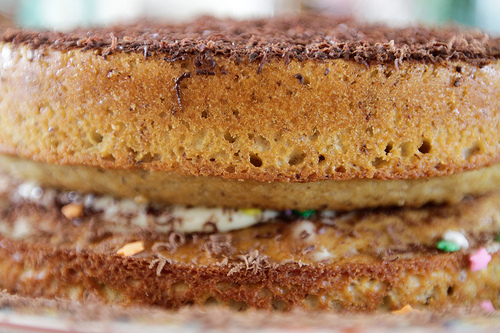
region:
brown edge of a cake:
[2, 43, 493, 174]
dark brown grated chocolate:
[20, 16, 492, 73]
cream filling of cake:
[7, 175, 289, 244]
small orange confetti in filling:
[57, 200, 161, 257]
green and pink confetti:
[432, 236, 493, 270]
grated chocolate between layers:
[146, 224, 277, 275]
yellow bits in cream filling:
[232, 204, 263, 225]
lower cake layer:
[4, 206, 499, 318]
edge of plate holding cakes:
[0, 296, 495, 330]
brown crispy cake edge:
[8, 234, 488, 286]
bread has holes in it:
[81, 114, 161, 166]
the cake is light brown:
[3, 36, 491, 221]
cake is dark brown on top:
[86, 1, 491, 56]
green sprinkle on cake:
[422, 220, 459, 261]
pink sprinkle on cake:
[468, 236, 499, 295]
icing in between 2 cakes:
[17, 170, 298, 266]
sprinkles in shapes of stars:
[433, 230, 495, 285]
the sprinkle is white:
[445, 222, 467, 251]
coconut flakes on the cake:
[139, 223, 291, 285]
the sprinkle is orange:
[58, 197, 93, 231]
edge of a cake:
[213, 25, 305, 152]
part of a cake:
[263, 241, 310, 278]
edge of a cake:
[190, 262, 263, 311]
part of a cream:
[435, 224, 457, 246]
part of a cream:
[434, 215, 465, 253]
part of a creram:
[203, 195, 238, 229]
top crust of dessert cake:
[103, 22, 420, 102]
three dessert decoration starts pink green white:
[431, 221, 494, 282]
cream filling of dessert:
[55, 180, 284, 247]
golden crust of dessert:
[37, 60, 184, 155]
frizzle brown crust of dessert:
[152, 31, 222, 131]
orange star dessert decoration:
[111, 240, 158, 267]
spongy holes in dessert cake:
[201, 94, 289, 171]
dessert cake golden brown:
[70, 22, 412, 319]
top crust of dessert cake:
[166, 11, 377, 58]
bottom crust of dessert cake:
[174, 256, 349, 321]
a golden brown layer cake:
[0, 13, 495, 332]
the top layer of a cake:
[0, 10, 488, 205]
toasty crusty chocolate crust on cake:
[0, 20, 495, 60]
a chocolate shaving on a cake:
[171, 73, 191, 109]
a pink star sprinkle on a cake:
[468, 249, 490, 274]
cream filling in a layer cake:
[36, 210, 274, 235]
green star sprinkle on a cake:
[433, 233, 455, 257]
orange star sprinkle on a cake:
[119, 239, 146, 258]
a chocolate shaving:
[153, 228, 190, 253]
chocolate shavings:
[232, 253, 274, 279]